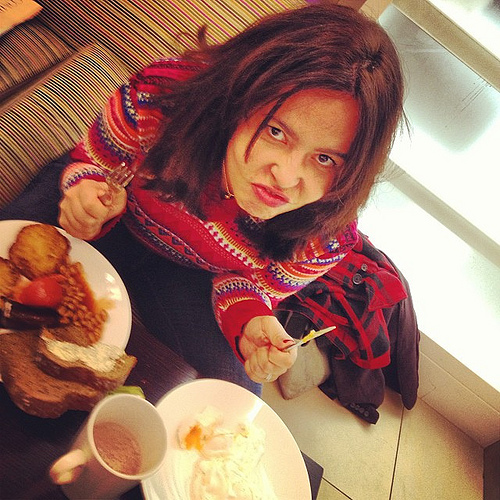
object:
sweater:
[65, 62, 358, 362]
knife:
[281, 326, 336, 351]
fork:
[98, 162, 134, 205]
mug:
[48, 393, 166, 500]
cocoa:
[94, 421, 139, 472]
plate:
[139, 377, 313, 500]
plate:
[1, 220, 133, 371]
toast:
[0, 332, 96, 417]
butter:
[45, 341, 124, 373]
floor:
[262, 380, 483, 499]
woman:
[0, 0, 404, 393]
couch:
[0, 1, 359, 205]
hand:
[58, 179, 127, 239]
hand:
[239, 316, 297, 383]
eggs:
[178, 408, 216, 452]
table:
[1, 328, 323, 500]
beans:
[89, 332, 94, 342]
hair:
[139, 0, 402, 257]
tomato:
[20, 278, 62, 306]